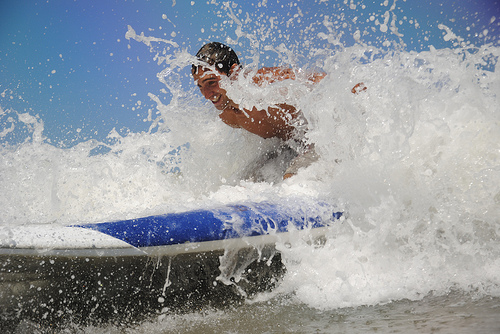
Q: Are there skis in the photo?
A: No, there are no skis.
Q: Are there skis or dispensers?
A: No, there are no skis or dispensers.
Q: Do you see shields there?
A: No, there are no shields.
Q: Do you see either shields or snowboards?
A: No, there are no shields or snowboards.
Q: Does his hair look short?
A: Yes, the hair is short.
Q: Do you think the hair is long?
A: No, the hair is short.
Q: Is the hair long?
A: No, the hair is short.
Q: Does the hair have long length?
A: No, the hair is short.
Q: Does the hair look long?
A: No, the hair is short.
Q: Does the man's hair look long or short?
A: The hair is short.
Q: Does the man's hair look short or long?
A: The hair is short.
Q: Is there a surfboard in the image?
A: Yes, there is a surfboard.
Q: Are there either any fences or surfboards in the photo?
A: Yes, there is a surfboard.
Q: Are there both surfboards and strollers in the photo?
A: No, there is a surfboard but no strollers.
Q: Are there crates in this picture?
A: No, there are no crates.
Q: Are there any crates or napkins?
A: No, there are no crates or napkins.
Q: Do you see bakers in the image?
A: No, there are no bakers.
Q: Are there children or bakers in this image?
A: No, there are no bakers or children.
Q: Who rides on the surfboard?
A: The man rides on the surfboard.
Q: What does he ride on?
A: The man rides on the surf board.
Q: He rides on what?
A: The man rides on the surf board.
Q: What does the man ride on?
A: The man rides on the surf board.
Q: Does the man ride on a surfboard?
A: Yes, the man rides on a surfboard.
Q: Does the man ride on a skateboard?
A: No, the man rides on a surfboard.